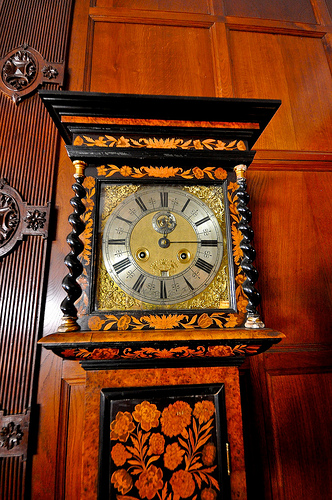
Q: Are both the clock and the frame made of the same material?
A: Yes, both the clock and the frame are made of wood.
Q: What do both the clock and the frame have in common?
A: The material, both the clock and the frame are wooden.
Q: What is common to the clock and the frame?
A: The material, both the clock and the frame are wooden.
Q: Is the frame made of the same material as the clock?
A: Yes, both the frame and the clock are made of wood.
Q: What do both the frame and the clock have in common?
A: The material, both the frame and the clock are wooden.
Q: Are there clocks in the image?
A: Yes, there is a clock.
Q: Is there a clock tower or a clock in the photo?
A: Yes, there is a clock.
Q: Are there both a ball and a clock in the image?
A: No, there is a clock but no balls.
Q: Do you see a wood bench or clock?
A: Yes, there is a wood clock.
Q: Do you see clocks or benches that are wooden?
A: Yes, the clock is wooden.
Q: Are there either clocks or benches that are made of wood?
A: Yes, the clock is made of wood.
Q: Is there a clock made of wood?
A: Yes, there is a clock that is made of wood.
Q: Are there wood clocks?
A: Yes, there is a clock that is made of wood.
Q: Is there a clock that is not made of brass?
A: Yes, there is a clock that is made of wood.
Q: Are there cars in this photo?
A: No, there are no cars.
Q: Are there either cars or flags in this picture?
A: No, there are no cars or flags.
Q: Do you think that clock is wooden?
A: Yes, the clock is wooden.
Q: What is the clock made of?
A: The clock is made of wood.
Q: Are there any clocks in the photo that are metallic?
A: No, there is a clock but it is wooden.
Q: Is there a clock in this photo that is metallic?
A: No, there is a clock but it is wooden.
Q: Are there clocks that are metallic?
A: No, there is a clock but it is wooden.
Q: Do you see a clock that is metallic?
A: No, there is a clock but it is wooden.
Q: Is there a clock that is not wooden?
A: No, there is a clock but it is wooden.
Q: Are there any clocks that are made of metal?
A: No, there is a clock but it is made of wood.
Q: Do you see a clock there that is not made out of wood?
A: No, there is a clock but it is made of wood.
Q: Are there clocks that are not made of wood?
A: No, there is a clock but it is made of wood.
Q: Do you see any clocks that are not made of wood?
A: No, there is a clock but it is made of wood.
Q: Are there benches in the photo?
A: No, there are no benches.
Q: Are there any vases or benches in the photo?
A: No, there are no benches or vases.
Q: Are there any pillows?
A: No, there are no pillows.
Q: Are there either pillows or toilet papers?
A: No, there are no pillows or toilet papers.